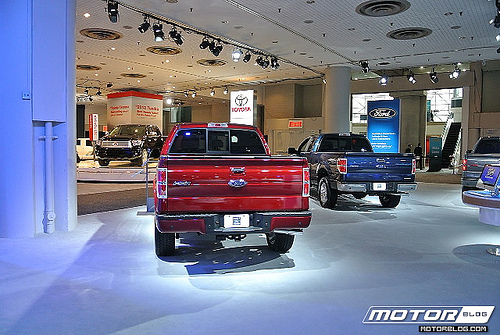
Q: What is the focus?
A: Truck dealership.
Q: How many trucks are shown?
A: 5.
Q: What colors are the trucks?
A: Red, blue, grey, white, black.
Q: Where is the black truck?
A: In display stage.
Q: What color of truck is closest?
A: Red.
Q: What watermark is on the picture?
A: Motorblog.com.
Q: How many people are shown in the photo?
A: 0.